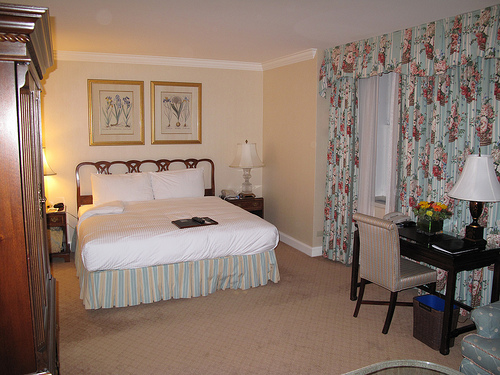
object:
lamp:
[446, 147, 500, 248]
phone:
[382, 211, 411, 224]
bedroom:
[0, 0, 500, 374]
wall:
[263, 47, 317, 258]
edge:
[312, 48, 317, 259]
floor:
[50, 240, 476, 374]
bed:
[75, 158, 281, 310]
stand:
[219, 195, 265, 219]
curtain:
[320, 3, 499, 315]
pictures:
[86, 78, 203, 147]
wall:
[40, 61, 262, 245]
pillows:
[90, 166, 206, 206]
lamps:
[41, 139, 266, 200]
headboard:
[75, 158, 215, 206]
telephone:
[221, 189, 237, 198]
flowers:
[412, 200, 456, 222]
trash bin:
[412, 292, 461, 351]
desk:
[350, 230, 500, 355]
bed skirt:
[74, 234, 281, 310]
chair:
[351, 213, 438, 335]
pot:
[418, 218, 444, 233]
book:
[171, 216, 219, 229]